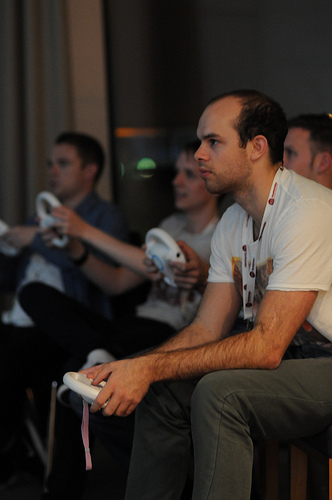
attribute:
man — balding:
[123, 90, 331, 496]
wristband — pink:
[69, 388, 111, 472]